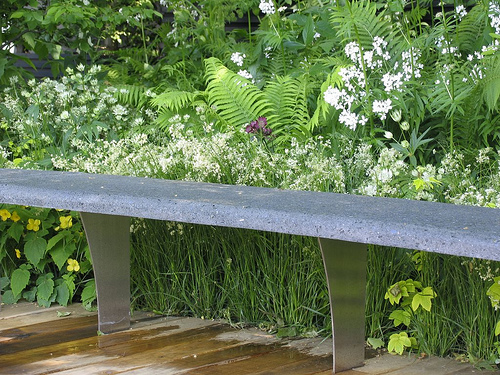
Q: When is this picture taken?
A: Day time.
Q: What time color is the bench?
A: Silver.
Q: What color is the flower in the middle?
A: Purple.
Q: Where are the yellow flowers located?
A: Bottom left.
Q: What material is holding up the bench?
A: Steel.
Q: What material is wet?
A: Wood.